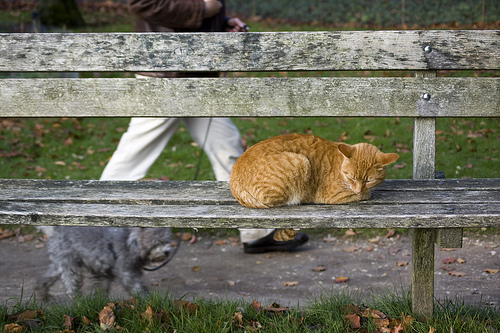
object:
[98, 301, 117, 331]
leaf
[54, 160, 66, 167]
leaf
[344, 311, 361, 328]
leaf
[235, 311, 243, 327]
leaf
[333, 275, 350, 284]
leaf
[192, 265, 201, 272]
leaf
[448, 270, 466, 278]
leaf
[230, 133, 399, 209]
cat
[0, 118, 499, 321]
ground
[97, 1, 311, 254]
person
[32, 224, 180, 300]
dog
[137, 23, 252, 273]
leash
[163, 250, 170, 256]
nose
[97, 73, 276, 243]
pants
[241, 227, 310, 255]
sandal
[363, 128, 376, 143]
leaf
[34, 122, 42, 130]
leaf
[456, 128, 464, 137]
leaf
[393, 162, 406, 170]
leaf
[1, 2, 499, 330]
park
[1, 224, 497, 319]
sidewalk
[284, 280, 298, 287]
leaf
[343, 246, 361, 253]
leaf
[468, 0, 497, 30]
shrub